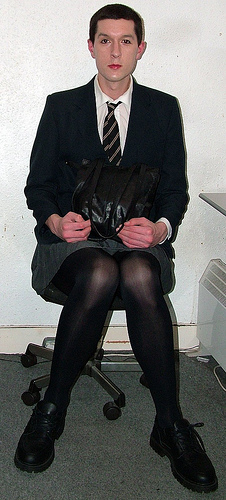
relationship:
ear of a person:
[134, 39, 147, 60] [12, 1, 219, 494]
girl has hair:
[13, 4, 218, 493] [88, 3, 142, 47]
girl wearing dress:
[13, 4, 218, 489] [32, 228, 175, 294]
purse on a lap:
[68, 156, 160, 239] [20, 210, 215, 322]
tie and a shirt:
[102, 100, 122, 166] [91, 72, 134, 170]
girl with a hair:
[13, 4, 218, 489] [89, 3, 142, 47]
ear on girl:
[85, 35, 96, 63] [13, 4, 218, 489]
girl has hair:
[13, 4, 218, 489] [77, 1, 145, 29]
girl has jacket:
[13, 4, 218, 493] [24, 74, 189, 258]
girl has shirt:
[13, 4, 218, 493] [91, 72, 134, 164]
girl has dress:
[13, 4, 218, 493] [30, 243, 174, 298]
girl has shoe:
[13, 4, 218, 493] [11, 399, 65, 472]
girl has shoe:
[13, 4, 218, 493] [147, 413, 218, 493]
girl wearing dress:
[13, 4, 218, 489] [32, 238, 173, 289]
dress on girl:
[30, 235, 176, 295] [13, 4, 218, 489]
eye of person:
[97, 37, 111, 42] [12, 1, 219, 494]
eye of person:
[121, 35, 136, 50] [12, 1, 219, 494]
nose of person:
[109, 43, 120, 58] [20, 2, 198, 183]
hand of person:
[113, 215, 158, 249] [12, 1, 219, 494]